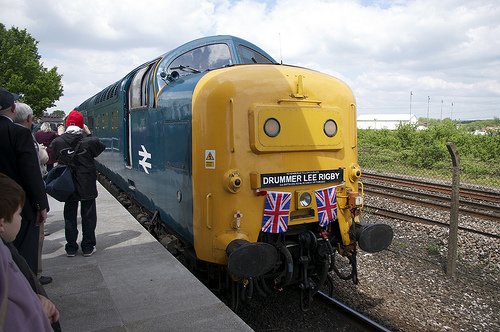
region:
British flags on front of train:
[256, 177, 342, 234]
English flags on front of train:
[255, 182, 347, 236]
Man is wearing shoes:
[61, 242, 97, 257]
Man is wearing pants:
[59, 195, 99, 254]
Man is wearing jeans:
[59, 192, 99, 257]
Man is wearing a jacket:
[47, 132, 107, 200]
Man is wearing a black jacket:
[50, 133, 104, 198]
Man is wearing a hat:
[65, 110, 86, 129]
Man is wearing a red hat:
[62, 105, 87, 129]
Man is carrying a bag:
[43, 135, 88, 199]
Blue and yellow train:
[57, 28, 397, 310]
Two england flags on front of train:
[260, 176, 367, 247]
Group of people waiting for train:
[0, 90, 107, 331]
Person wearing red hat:
[65, 111, 86, 125]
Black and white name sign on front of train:
[255, 162, 360, 188]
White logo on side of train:
[124, 136, 172, 178]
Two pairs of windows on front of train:
[161, 32, 282, 81]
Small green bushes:
[368, 113, 494, 175]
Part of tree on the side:
[0, 18, 75, 120]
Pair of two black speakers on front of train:
[224, 214, 400, 289]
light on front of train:
[250, 108, 295, 151]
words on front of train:
[257, 163, 347, 199]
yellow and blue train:
[136, 96, 254, 193]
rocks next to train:
[401, 254, 442, 304]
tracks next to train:
[404, 173, 448, 233]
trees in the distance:
[391, 113, 454, 165]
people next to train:
[1, 91, 125, 201]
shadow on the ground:
[108, 214, 142, 262]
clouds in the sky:
[391, 6, 488, 74]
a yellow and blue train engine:
[83, 31, 387, 298]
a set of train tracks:
[244, 279, 386, 329]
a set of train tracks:
[361, 185, 498, 243]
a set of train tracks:
[361, 168, 498, 210]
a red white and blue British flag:
[261, 187, 291, 234]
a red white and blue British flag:
[312, 184, 342, 228]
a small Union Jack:
[261, 189, 291, 234]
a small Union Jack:
[312, 186, 344, 227]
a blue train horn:
[157, 69, 179, 83]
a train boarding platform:
[0, 171, 253, 330]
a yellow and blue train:
[68, 45, 358, 265]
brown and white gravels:
[390, 265, 499, 328]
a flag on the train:
[265, 189, 345, 230]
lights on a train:
[262, 116, 337, 139]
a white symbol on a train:
[136, 145, 150, 175]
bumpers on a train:
[226, 233, 288, 285]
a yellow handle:
[201, 190, 214, 232]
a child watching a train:
[1, 188, 58, 330]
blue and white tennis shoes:
[82, 240, 100, 257]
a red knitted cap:
[63, 111, 88, 127]